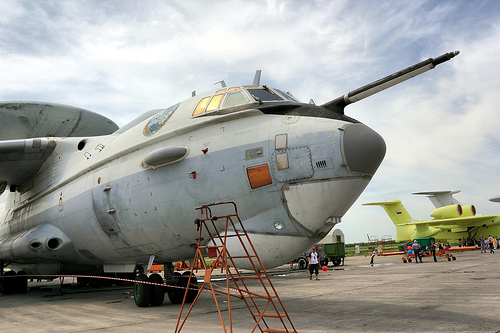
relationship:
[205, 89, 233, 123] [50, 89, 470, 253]
window on airplane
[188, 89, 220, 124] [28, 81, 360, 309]
window on airplane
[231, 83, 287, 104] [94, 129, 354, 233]
window on airplane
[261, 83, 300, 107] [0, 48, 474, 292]
window on aircraft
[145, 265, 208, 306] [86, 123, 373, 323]
wheels on plane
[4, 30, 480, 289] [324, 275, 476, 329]
aircraft on a runway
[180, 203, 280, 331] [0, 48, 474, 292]
stepladder get up to aircraft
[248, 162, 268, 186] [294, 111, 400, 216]
hatch by nose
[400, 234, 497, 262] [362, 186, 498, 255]
people by plane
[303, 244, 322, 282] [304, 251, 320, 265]
man wearing shirt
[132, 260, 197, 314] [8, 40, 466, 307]
wheels of an aircraft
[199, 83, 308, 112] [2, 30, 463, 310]
cockpit of a plane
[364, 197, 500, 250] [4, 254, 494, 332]
airplane lined up on runway